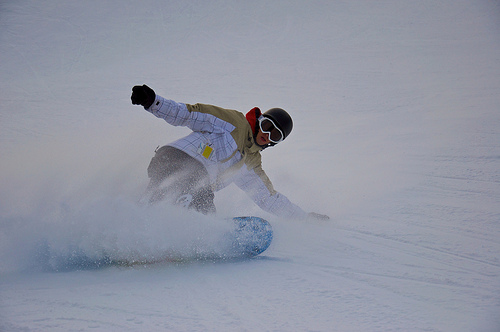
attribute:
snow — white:
[1, 2, 496, 331]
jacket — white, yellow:
[149, 98, 306, 220]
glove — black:
[130, 84, 155, 106]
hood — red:
[246, 107, 261, 133]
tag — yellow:
[203, 144, 214, 161]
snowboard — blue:
[40, 216, 272, 266]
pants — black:
[148, 147, 215, 218]